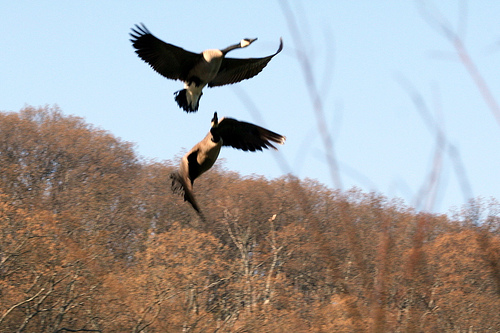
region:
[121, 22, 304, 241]
two geese flying in the air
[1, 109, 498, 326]
trees with brown colored leaves in the distance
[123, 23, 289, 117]
a canadian goose flying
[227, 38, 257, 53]
the head of a goose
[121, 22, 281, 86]
the wing span of the goose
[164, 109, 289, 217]
the goose is flapping its wings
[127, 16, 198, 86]
the right wing of a goose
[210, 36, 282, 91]
the left wing of a goose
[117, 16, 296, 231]
a goose chasing another goose in the air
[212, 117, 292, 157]
the left wing of a flying goose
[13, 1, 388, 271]
canadian geese are in flight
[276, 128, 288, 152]
the tips of the wing feathers are white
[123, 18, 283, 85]
the wings of the bird are spread out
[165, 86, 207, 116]
the tail feathers are black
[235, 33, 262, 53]
the goose has a white cheek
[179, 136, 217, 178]
the bird's body is white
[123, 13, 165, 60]
the wing feathers are splayed out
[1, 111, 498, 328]
the leaves of the trees have turned brown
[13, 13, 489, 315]
the season is changing and the geese are migrating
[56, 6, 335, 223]
the geese will join a flock going south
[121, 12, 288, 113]
A Canada goose flying with its wings outstretched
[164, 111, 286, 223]
A Canada goose mid-flight underneath another goose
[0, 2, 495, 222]
Pale blue sky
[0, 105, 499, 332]
Trees covered in autumn foliage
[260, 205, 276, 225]
Light colored bird sitting in tree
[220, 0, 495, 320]
Stray blurry branches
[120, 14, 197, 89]
One Canada goose wing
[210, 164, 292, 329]
Autumnal tree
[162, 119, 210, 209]
Sunlight gilding the top of a Canada goose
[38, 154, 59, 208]
Blue sky peeking through tree branches and autumnal foliage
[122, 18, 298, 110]
black and white bird flying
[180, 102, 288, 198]
black and white bird flying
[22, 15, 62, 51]
white clouds in blue sky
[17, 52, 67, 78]
white clouds in blue sky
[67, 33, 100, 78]
white clouds in blue sky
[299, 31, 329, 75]
white clouds in blue sky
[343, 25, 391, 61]
white clouds in blue sky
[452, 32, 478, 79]
white clouds in blue sky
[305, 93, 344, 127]
white clouds in blue sky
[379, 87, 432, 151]
white clouds in blue sky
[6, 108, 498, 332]
so many trees with brown leaves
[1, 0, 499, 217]
the sunny blue sky above the clouds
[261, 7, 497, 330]
some tall weeds before the trees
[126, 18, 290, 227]
two birds flying in the air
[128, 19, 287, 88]
the spread out wings of the top bird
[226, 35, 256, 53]
the long neck and head of the bird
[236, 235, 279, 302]
some visible branches of the trees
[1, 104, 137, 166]
a big pile of brown leaves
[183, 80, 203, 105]
the white feathers of the bird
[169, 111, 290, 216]
the bird on the bottom